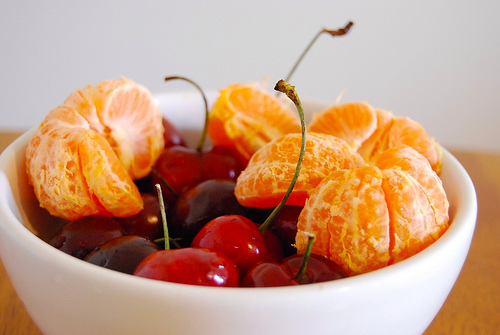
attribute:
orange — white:
[29, 74, 159, 245]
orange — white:
[299, 152, 454, 279]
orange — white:
[234, 126, 364, 226]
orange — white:
[313, 102, 443, 195]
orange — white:
[293, 158, 462, 285]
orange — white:
[235, 129, 378, 222]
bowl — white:
[0, 76, 474, 333]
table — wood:
[2, 121, 498, 333]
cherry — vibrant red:
[196, 209, 282, 277]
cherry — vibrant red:
[192, 201, 276, 273]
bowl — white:
[56, 200, 445, 319]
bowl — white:
[17, 145, 485, 332]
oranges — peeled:
[249, 92, 437, 247]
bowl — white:
[0, 213, 481, 329]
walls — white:
[23, 8, 453, 96]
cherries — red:
[141, 204, 291, 277]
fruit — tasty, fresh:
[92, 115, 357, 261]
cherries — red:
[130, 197, 309, 278]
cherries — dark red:
[70, 190, 242, 282]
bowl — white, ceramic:
[6, 229, 474, 332]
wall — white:
[31, 20, 281, 141]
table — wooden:
[425, 208, 496, 319]